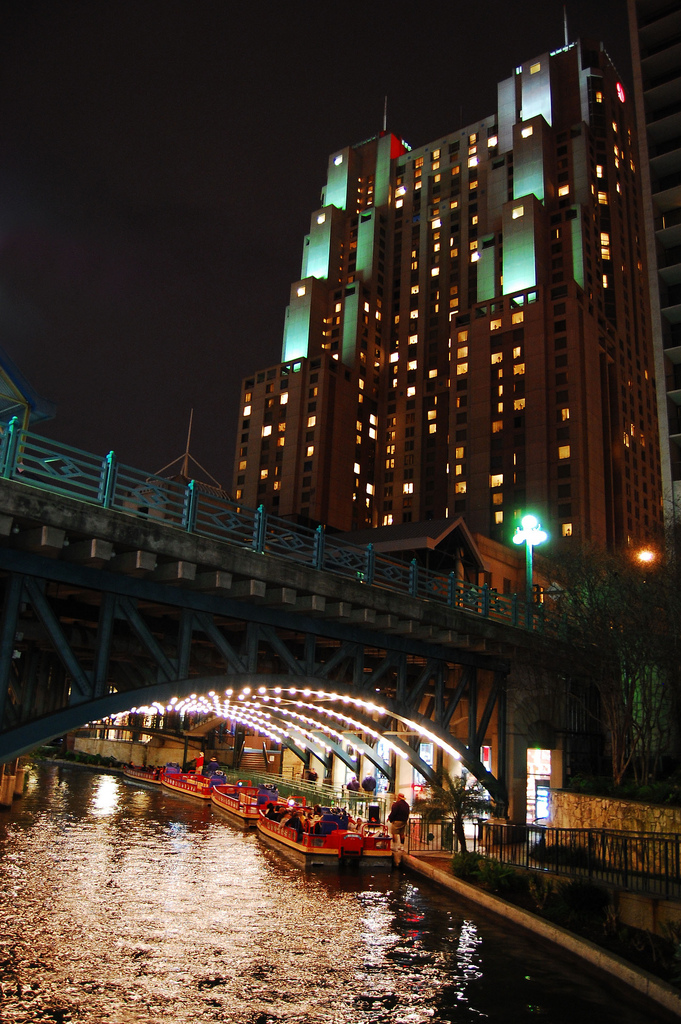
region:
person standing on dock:
[382, 793, 427, 856]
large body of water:
[395, 895, 462, 952]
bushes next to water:
[551, 878, 618, 925]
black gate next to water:
[482, 822, 679, 893]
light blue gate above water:
[0, 419, 425, 583]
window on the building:
[295, 283, 309, 295]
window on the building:
[240, 402, 258, 419]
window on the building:
[447, 164, 463, 177]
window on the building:
[512, 361, 529, 374]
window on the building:
[592, 89, 605, 105]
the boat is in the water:
[256, 802, 394, 864]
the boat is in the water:
[210, 778, 270, 827]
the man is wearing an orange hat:
[389, 792, 410, 845]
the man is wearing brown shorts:
[389, 792, 410, 846]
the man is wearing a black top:
[387, 792, 410, 846]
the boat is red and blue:
[256, 792, 395, 873]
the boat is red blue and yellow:
[210, 775, 267, 827]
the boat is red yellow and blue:
[162, 752, 215, 800]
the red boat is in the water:
[122, 762, 161, 786]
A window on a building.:
[514, 395, 528, 410]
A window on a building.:
[452, 360, 469, 371]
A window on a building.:
[455, 346, 471, 362]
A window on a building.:
[454, 328, 462, 339]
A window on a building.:
[488, 319, 499, 330]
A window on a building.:
[513, 311, 525, 322]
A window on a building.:
[553, 317, 572, 332]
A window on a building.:
[553, 334, 566, 343]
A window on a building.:
[554, 351, 565, 362]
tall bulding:
[233, 8, 630, 832]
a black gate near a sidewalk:
[401, 811, 680, 894]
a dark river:
[3, 755, 670, 1020]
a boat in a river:
[257, 796, 397, 867]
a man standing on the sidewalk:
[387, 790, 409, 842]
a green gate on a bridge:
[0, 417, 581, 640]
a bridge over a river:
[2, 411, 586, 848]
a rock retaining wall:
[545, 787, 680, 874]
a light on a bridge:
[509, 512, 550, 616]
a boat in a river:
[210, 777, 275, 825]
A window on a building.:
[425, 409, 436, 417]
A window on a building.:
[407, 385, 414, 395]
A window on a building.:
[408, 359, 417, 372]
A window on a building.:
[408, 335, 417, 345]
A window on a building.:
[406, 309, 422, 318]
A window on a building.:
[410, 285, 419, 295]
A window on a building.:
[431, 265, 438, 278]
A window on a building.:
[511, 204, 524, 217]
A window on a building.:
[492, 420, 501, 432]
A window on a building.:
[493, 470, 501, 483]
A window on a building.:
[455, 481, 465, 489]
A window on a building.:
[450, 463, 457, 473]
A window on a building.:
[452, 446, 460, 457]